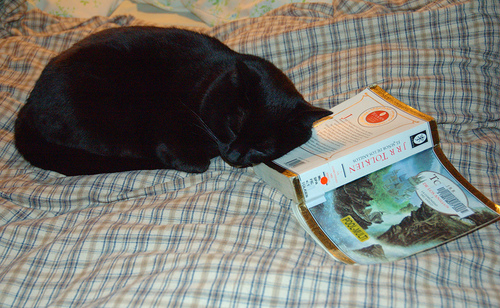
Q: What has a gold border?
A: A white book.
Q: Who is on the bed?
A: The cat.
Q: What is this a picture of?
A: The head of the cat.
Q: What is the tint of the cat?
A: Black.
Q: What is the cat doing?
A: Laying on the cot.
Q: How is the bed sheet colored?
A: Gray.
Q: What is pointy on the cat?
A: Ears.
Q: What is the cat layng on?
A: Book.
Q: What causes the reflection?
A: Light.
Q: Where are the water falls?
A: Book cover.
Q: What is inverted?
A: Book.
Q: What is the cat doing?
A: Sleeping.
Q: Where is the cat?
A: Bed.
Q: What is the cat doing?
A: Laying on book.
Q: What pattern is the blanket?
A: Plaid.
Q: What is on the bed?
A: A book.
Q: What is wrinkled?
A: The blanket.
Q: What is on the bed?
A: A cat.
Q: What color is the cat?
A: Black.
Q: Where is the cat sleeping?
A: On Bed.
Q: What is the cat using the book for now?
A: Pillow.